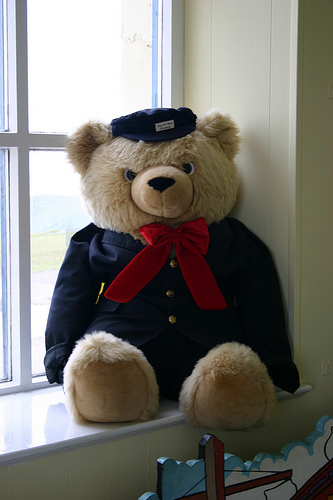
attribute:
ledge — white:
[3, 347, 316, 457]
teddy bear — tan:
[43, 105, 298, 433]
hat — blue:
[108, 104, 191, 147]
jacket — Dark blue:
[43, 214, 297, 383]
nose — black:
[146, 174, 176, 193]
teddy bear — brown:
[28, 95, 293, 446]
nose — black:
[142, 168, 188, 197]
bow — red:
[98, 215, 224, 310]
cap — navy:
[109, 104, 197, 143]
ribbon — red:
[101, 219, 235, 314]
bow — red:
[134, 221, 210, 259]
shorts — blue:
[92, 319, 229, 370]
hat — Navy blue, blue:
[108, 104, 199, 146]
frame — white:
[1, 9, 191, 401]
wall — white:
[176, 9, 310, 380]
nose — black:
[141, 173, 180, 199]